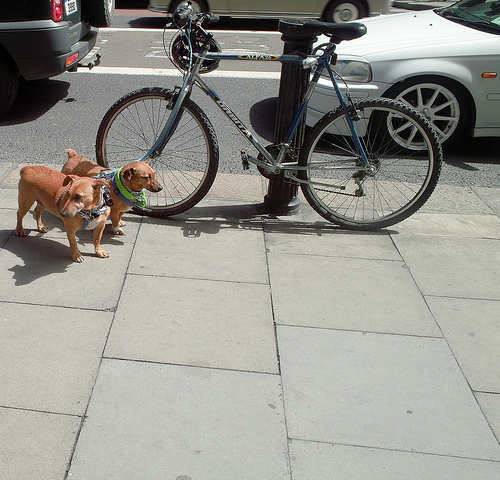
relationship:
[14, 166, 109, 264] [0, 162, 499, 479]
dog standing sidewalk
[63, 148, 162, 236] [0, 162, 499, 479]
dog standing sidewalk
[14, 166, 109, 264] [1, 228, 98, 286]
dog has shadow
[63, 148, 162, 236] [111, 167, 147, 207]
dog wearing collar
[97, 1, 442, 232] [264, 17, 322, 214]
bike leaning on post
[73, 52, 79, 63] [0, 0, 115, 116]
light attached to car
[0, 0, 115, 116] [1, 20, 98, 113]
car has bottom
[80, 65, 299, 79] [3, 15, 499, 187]
line painted on road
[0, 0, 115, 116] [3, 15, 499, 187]
car on road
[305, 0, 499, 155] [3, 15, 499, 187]
car on road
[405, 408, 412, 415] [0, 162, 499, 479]
mark on top of sidewalk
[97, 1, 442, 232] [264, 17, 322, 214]
bike attached to post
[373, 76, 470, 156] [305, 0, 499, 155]
tire attached to car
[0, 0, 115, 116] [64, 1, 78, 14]
car has license plate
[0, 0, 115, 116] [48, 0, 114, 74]
car has back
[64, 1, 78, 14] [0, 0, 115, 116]
license plate attached to car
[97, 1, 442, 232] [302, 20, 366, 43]
bike has seat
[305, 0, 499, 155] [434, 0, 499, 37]
car has windshield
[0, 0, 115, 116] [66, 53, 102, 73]
car has tow hitch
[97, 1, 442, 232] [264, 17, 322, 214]
bike leaning against post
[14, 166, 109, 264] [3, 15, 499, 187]
dog standing in road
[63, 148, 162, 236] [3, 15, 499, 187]
dog standing in road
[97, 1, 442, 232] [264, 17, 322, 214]
bike parked near post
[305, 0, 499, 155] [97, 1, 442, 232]
car parked near bike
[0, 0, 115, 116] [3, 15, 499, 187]
car parked in road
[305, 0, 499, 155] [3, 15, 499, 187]
car parked in road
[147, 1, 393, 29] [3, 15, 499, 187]
car parked in road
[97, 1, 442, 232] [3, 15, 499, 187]
bike parked in road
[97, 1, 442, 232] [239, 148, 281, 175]
bike has pedal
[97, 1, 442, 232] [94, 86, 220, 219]
bike has tyre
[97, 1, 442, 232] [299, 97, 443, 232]
bike has tyre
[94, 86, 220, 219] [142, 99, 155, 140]
tyre has spoke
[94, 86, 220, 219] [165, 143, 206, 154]
tyre has spoke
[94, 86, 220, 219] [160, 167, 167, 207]
tyre has spoke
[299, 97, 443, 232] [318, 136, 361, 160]
tyre has spoke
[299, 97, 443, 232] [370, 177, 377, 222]
tyre has spoke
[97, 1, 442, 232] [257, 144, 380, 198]
bike has chain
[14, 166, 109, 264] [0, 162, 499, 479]
dog standing on sidewalk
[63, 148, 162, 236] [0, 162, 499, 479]
dog standing on sidewalk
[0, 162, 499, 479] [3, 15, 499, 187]
sidewalk next to road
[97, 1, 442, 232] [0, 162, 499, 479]
bike parked on sidewalk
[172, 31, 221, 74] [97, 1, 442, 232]
helmet hanging on bike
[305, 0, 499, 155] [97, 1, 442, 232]
car behind bike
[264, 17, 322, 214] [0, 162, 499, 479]
post embedded in sidewalk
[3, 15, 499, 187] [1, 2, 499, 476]
road located in city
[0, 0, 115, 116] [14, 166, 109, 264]
car behind dog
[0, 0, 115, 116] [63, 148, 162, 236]
car behind dog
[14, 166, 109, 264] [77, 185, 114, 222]
dog has collar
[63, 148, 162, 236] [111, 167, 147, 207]
dog has collar